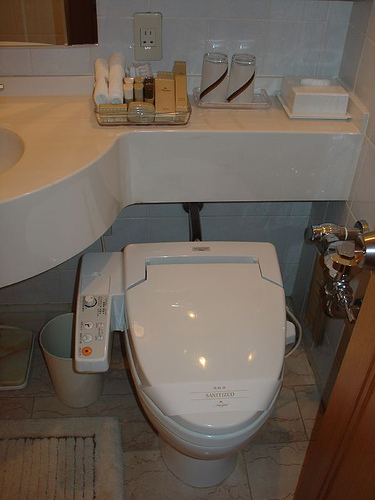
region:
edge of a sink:
[245, 128, 266, 147]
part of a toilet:
[249, 351, 286, 364]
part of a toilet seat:
[214, 372, 222, 442]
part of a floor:
[127, 439, 133, 462]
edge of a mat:
[83, 427, 87, 448]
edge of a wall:
[317, 369, 332, 375]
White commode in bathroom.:
[119, 224, 309, 476]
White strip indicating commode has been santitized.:
[126, 373, 294, 431]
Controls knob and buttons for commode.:
[70, 271, 111, 370]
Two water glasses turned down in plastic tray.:
[190, 51, 271, 114]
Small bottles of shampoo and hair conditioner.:
[123, 73, 158, 99]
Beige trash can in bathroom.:
[35, 311, 119, 411]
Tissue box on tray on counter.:
[274, 67, 360, 127]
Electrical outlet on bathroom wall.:
[126, 11, 169, 62]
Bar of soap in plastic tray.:
[127, 99, 158, 123]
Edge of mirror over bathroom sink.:
[5, 8, 108, 55]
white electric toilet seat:
[72, 236, 294, 481]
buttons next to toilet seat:
[78, 259, 170, 380]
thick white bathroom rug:
[5, 406, 155, 497]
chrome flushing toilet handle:
[300, 214, 373, 338]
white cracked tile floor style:
[236, 430, 310, 498]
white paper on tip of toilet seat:
[133, 350, 289, 427]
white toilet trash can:
[37, 304, 127, 413]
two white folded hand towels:
[91, 50, 137, 114]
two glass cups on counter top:
[197, 48, 273, 106]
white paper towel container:
[276, 62, 360, 128]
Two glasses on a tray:
[187, 45, 263, 118]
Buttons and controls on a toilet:
[73, 276, 118, 393]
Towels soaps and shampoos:
[90, 64, 200, 123]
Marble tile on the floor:
[95, 386, 287, 498]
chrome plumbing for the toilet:
[300, 210, 365, 328]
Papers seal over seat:
[129, 364, 301, 440]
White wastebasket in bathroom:
[37, 317, 111, 403]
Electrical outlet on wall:
[126, 14, 172, 65]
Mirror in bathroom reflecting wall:
[6, 5, 99, 49]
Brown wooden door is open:
[293, 264, 374, 498]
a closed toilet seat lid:
[77, 244, 295, 486]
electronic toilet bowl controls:
[72, 251, 120, 378]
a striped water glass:
[197, 50, 231, 106]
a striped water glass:
[227, 53, 254, 102]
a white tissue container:
[274, 74, 347, 116]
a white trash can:
[33, 308, 109, 412]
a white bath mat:
[1, 407, 121, 498]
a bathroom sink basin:
[0, 111, 35, 182]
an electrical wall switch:
[129, 10, 163, 61]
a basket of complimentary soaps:
[93, 57, 187, 127]